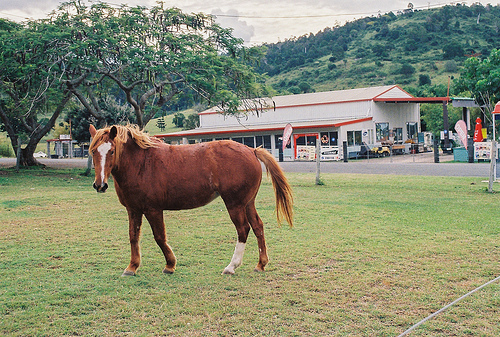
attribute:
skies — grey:
[0, 0, 497, 62]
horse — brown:
[79, 122, 238, 234]